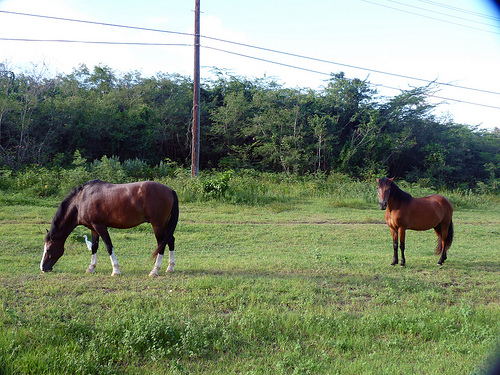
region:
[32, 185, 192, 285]
horse standing in field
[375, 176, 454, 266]
horse standing in field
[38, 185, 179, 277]
brown horse with socks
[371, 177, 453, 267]
brown horse with socks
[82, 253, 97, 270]
white socked foot of horse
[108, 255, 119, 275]
white socked foot of horse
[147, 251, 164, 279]
white socked foot of horse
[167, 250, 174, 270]
white socked foot of horse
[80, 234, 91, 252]
white bird behind horse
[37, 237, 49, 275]
white face of horse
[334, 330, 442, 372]
patch of green grass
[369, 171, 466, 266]
brown horse standing on grass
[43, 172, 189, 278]
horse eating the grass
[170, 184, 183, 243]
black tail on horse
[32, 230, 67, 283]
head of the horse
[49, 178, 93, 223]
black mane on horses neck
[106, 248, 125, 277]
horse's left front foot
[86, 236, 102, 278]
horse's right front foot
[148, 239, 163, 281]
horses left back leg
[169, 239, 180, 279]
horses right back leg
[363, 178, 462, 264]
a brown horse with a black mane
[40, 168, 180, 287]
a brown horse with a black mane and white hooves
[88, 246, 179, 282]
white hooves on a horse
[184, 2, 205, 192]
a pole in the ground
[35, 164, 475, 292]
two horses standing in a field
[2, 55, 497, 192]
tall trees behind the pole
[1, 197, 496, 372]
a field of grass on the ground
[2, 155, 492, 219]
bushes on the ground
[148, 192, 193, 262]
tail of a horse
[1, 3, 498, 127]
telephone wires in the sky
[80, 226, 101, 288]
leg of a horse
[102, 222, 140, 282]
leg of a horse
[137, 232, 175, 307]
leg of a horse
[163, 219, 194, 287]
leg of a horse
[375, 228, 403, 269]
leg of a horse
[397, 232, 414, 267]
leg of a horse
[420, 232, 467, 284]
leg of a horse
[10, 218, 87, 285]
head of a horse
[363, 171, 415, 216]
head of a horse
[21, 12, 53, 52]
white clouds in blue sky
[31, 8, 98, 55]
white clouds in blue sky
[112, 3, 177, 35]
white clouds in blue sky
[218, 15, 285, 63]
white clouds in blue sky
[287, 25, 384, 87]
white clouds in blue sky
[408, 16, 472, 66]
white clouds in blue sky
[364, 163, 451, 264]
brown horse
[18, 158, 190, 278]
horse